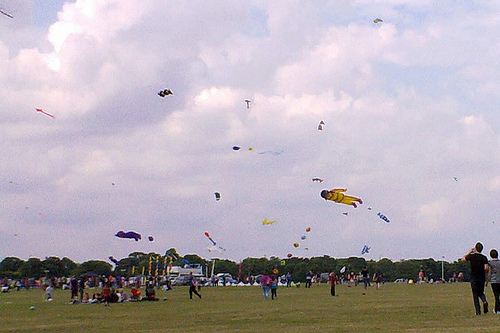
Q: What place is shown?
A: It is a park.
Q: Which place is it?
A: It is a park.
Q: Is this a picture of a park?
A: Yes, it is showing a park.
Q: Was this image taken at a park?
A: Yes, it was taken in a park.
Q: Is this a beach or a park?
A: It is a park.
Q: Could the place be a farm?
A: No, it is a park.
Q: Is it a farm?
A: No, it is a park.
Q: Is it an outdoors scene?
A: Yes, it is outdoors.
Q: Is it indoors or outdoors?
A: It is outdoors.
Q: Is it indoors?
A: No, it is outdoors.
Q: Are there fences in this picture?
A: No, there are no fences.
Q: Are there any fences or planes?
A: No, there are no fences or planes.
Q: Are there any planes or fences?
A: No, there are no fences or planes.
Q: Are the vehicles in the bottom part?
A: Yes, the vehicles are in the bottom of the image.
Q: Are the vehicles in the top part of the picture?
A: No, the vehicles are in the bottom of the image.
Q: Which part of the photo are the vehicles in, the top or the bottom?
A: The vehicles are in the bottom of the image.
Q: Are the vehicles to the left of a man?
A: Yes, the vehicles are to the left of a man.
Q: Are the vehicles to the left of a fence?
A: No, the vehicles are to the left of a man.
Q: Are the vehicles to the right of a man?
A: Yes, the vehicles are to the right of a man.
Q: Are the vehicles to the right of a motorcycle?
A: No, the vehicles are to the right of a man.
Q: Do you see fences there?
A: No, there are no fences.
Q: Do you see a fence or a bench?
A: No, there are no fences or benches.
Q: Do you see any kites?
A: Yes, there is a kite.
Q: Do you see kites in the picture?
A: Yes, there is a kite.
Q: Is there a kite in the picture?
A: Yes, there is a kite.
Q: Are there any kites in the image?
A: Yes, there is a kite.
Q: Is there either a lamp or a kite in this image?
A: Yes, there is a kite.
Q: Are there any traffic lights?
A: No, there are no traffic lights.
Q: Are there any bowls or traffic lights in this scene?
A: No, there are no traffic lights or bowls.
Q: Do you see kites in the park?
A: Yes, there is a kite in the park.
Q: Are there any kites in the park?
A: Yes, there is a kite in the park.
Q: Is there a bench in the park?
A: No, there is a kite in the park.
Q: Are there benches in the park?
A: No, there is a kite in the park.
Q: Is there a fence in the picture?
A: No, there are no fences.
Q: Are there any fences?
A: No, there are no fences.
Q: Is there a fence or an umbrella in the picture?
A: No, there are no fences or umbrellas.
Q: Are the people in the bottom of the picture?
A: Yes, the people are in the bottom of the image.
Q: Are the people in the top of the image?
A: No, the people are in the bottom of the image.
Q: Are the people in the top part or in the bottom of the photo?
A: The people are in the bottom of the image.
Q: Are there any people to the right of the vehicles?
A: Yes, there are people to the right of the vehicles.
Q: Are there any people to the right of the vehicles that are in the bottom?
A: Yes, there are people to the right of the vehicles.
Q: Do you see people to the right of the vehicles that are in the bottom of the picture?
A: Yes, there are people to the right of the vehicles.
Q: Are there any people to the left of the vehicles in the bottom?
A: No, the people are to the right of the vehicles.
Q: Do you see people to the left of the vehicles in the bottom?
A: No, the people are to the right of the vehicles.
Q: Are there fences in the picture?
A: No, there are no fences.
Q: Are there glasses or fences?
A: No, there are no fences or glasses.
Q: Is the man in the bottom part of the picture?
A: Yes, the man is in the bottom of the image.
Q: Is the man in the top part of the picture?
A: No, the man is in the bottom of the image.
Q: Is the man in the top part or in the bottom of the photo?
A: The man is in the bottom of the image.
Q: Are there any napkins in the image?
A: No, there are no napkins.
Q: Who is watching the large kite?
A: The couple is watching the kite.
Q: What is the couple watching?
A: The couple is watching the kite.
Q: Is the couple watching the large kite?
A: Yes, the couple is watching the kite.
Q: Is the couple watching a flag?
A: No, the couple is watching the kite.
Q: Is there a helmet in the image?
A: No, there are no helmets.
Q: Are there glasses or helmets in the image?
A: No, there are no helmets or glasses.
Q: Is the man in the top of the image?
A: No, the man is in the bottom of the image.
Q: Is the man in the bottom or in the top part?
A: The man is in the bottom of the image.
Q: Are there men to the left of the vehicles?
A: Yes, there is a man to the left of the vehicles.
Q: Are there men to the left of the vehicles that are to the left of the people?
A: Yes, there is a man to the left of the vehicles.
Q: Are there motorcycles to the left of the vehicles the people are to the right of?
A: No, there is a man to the left of the vehicles.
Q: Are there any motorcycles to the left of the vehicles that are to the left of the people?
A: No, there is a man to the left of the vehicles.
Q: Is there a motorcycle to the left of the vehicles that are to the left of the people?
A: No, there is a man to the left of the vehicles.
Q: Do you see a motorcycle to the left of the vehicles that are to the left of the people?
A: No, there is a man to the left of the vehicles.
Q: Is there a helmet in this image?
A: No, there are no helmets.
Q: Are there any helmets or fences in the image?
A: No, there are no helmets or fences.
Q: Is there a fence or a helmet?
A: No, there are no helmets or fences.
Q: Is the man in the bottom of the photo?
A: Yes, the man is in the bottom of the image.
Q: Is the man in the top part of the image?
A: No, the man is in the bottom of the image.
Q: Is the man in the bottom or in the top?
A: The man is in the bottom of the image.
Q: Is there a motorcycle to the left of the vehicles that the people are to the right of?
A: No, there is a man to the left of the vehicles.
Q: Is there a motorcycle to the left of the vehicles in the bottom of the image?
A: No, there is a man to the left of the vehicles.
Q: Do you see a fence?
A: No, there are no fences.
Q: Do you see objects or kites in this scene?
A: Yes, there is a kite.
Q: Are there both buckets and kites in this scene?
A: No, there is a kite but no buckets.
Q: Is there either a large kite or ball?
A: Yes, there is a large kite.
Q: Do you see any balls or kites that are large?
A: Yes, the kite is large.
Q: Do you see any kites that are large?
A: Yes, there is a large kite.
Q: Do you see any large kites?
A: Yes, there is a large kite.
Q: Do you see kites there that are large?
A: Yes, there is a kite that is large.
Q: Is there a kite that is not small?
A: Yes, there is a large kite.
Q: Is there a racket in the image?
A: No, there are no rackets.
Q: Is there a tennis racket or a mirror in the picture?
A: No, there are no rackets or mirrors.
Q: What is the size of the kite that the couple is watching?
A: The kite is large.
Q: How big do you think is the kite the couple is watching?
A: The kite is large.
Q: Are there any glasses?
A: No, there are no glasses.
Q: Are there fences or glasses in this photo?
A: No, there are no glasses or fences.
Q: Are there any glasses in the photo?
A: No, there are no glasses.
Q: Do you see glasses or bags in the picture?
A: No, there are no glasses or bags.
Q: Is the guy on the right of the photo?
A: Yes, the guy is on the right of the image.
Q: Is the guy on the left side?
A: No, the guy is on the right of the image.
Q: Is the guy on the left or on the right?
A: The guy is on the right of the image.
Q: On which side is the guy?
A: The guy is on the right of the image.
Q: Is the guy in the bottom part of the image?
A: Yes, the guy is in the bottom of the image.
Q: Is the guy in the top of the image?
A: No, the guy is in the bottom of the image.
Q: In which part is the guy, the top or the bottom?
A: The guy is in the bottom of the image.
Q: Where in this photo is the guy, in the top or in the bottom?
A: The guy is in the bottom of the image.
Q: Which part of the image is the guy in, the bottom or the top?
A: The guy is in the bottom of the image.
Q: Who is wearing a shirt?
A: The guy is wearing a shirt.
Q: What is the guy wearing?
A: The guy is wearing a shirt.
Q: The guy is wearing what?
A: The guy is wearing a shirt.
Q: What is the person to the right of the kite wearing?
A: The guy is wearing a shirt.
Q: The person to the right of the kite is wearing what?
A: The guy is wearing a shirt.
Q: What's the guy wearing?
A: The guy is wearing a shirt.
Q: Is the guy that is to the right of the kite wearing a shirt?
A: Yes, the guy is wearing a shirt.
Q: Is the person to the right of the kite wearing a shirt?
A: Yes, the guy is wearing a shirt.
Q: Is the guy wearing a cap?
A: No, the guy is wearing a shirt.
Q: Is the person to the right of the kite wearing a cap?
A: No, the guy is wearing a shirt.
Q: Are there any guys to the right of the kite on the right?
A: Yes, there is a guy to the right of the kite.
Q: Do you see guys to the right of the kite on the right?
A: Yes, there is a guy to the right of the kite.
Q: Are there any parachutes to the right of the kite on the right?
A: No, there is a guy to the right of the kite.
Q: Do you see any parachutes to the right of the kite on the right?
A: No, there is a guy to the right of the kite.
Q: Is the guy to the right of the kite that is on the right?
A: Yes, the guy is to the right of the kite.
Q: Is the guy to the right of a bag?
A: No, the guy is to the right of the kite.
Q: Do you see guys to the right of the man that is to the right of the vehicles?
A: Yes, there is a guy to the right of the man.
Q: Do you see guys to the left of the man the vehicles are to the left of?
A: No, the guy is to the right of the man.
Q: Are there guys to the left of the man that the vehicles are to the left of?
A: No, the guy is to the right of the man.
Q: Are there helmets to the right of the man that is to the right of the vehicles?
A: No, there is a guy to the right of the man.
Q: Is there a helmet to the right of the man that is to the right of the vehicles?
A: No, there is a guy to the right of the man.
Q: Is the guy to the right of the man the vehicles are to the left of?
A: Yes, the guy is to the right of the man.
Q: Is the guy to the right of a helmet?
A: No, the guy is to the right of the man.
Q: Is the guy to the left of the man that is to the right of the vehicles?
A: No, the guy is to the right of the man.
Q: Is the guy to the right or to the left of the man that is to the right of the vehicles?
A: The guy is to the right of the man.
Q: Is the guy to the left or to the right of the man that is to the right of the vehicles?
A: The guy is to the right of the man.